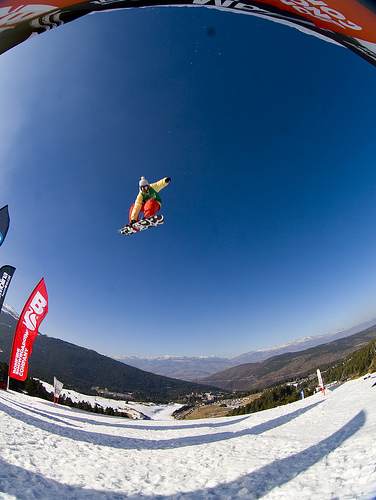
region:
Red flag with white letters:
[6, 276, 49, 389]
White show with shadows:
[46, 415, 323, 493]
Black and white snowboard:
[120, 212, 165, 237]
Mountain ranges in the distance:
[143, 327, 370, 381]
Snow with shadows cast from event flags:
[3, 406, 312, 449]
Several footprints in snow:
[5, 419, 304, 499]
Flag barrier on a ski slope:
[48, 371, 63, 403]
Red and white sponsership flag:
[8, 275, 47, 382]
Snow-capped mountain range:
[248, 322, 363, 351]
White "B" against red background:
[29, 288, 47, 316]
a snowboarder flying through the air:
[111, 173, 182, 239]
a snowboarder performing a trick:
[109, 165, 180, 238]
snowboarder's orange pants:
[111, 194, 165, 226]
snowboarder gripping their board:
[117, 173, 178, 242]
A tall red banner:
[6, 268, 51, 374]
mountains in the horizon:
[84, 343, 309, 372]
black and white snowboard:
[112, 211, 172, 236]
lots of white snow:
[36, 418, 355, 494]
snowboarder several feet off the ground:
[112, 171, 178, 237]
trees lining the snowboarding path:
[220, 340, 374, 417]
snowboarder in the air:
[106, 170, 192, 273]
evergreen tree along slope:
[254, 394, 260, 413]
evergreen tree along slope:
[274, 387, 282, 403]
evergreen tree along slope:
[246, 403, 253, 414]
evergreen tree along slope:
[338, 368, 347, 381]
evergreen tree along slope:
[362, 356, 363, 368]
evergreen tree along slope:
[236, 407, 245, 416]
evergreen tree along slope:
[233, 404, 241, 412]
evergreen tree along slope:
[232, 404, 238, 414]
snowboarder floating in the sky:
[113, 172, 176, 235]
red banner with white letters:
[9, 272, 54, 392]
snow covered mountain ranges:
[154, 330, 345, 364]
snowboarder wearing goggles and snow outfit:
[121, 168, 177, 220]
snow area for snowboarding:
[17, 392, 373, 492]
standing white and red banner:
[314, 367, 328, 394]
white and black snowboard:
[116, 209, 172, 236]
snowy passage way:
[51, 397, 265, 491]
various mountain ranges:
[45, 323, 346, 405]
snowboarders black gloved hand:
[160, 175, 175, 187]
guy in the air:
[50, 103, 251, 289]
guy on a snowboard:
[42, 138, 264, 466]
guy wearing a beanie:
[99, 154, 203, 253]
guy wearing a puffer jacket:
[109, 172, 189, 239]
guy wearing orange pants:
[107, 171, 190, 247]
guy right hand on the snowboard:
[95, 169, 199, 239]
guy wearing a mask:
[108, 162, 187, 239]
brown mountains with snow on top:
[46, 313, 304, 407]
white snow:
[58, 426, 327, 487]